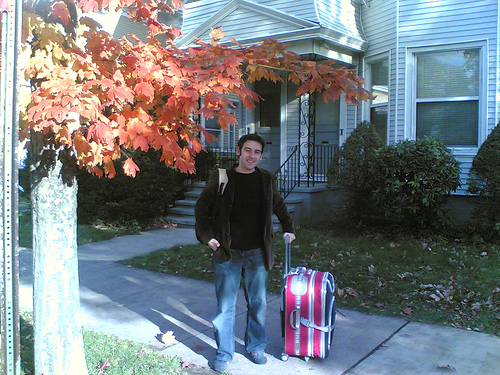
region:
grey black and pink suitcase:
[283, 235, 336, 357]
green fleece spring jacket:
[193, 166, 292, 269]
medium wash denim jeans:
[211, 250, 268, 357]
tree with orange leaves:
[23, 0, 373, 372]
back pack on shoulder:
[213, 167, 229, 211]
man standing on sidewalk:
[193, 133, 296, 370]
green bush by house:
[364, 139, 459, 232]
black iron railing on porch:
[273, 140, 341, 199]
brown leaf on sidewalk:
[160, 326, 175, 348]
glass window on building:
[402, 36, 484, 152]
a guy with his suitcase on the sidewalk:
[150, 121, 407, 373]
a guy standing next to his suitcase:
[188, 125, 343, 373]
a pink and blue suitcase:
[280, 235, 340, 365]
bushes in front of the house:
[326, 107, 438, 247]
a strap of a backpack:
[214, 165, 228, 198]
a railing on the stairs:
[274, 144, 302, 200]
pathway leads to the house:
[80, 223, 202, 263]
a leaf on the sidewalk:
[155, 328, 178, 345]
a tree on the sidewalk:
[21, 30, 366, 372]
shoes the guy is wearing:
[210, 346, 271, 373]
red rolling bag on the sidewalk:
[278, 233, 339, 364]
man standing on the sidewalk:
[192, 128, 299, 374]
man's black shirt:
[227, 164, 265, 257]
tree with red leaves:
[18, 0, 380, 372]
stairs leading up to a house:
[165, 164, 312, 249]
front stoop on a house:
[188, 155, 340, 193]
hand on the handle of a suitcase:
[276, 225, 298, 245]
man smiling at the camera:
[191, 130, 301, 374]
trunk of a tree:
[24, 127, 100, 374]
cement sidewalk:
[16, 240, 497, 373]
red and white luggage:
[281, 269, 342, 360]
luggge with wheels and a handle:
[285, 232, 333, 372]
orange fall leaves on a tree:
[91, 58, 173, 135]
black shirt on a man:
[221, 149, 259, 256]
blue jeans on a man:
[221, 249, 269, 373]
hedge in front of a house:
[355, 128, 472, 252]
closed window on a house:
[410, 23, 487, 157]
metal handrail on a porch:
[274, 75, 334, 207]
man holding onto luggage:
[261, 189, 332, 371]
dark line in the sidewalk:
[357, 330, 404, 372]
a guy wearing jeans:
[189, 128, 301, 373]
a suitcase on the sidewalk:
[276, 235, 340, 367]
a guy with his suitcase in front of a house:
[124, 9, 464, 373]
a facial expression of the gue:
[236, 131, 266, 170]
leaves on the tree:
[24, 3, 365, 177]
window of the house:
[402, 35, 489, 159]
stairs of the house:
[172, 179, 198, 226]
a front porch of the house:
[163, 2, 358, 189]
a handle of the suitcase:
[288, 306, 301, 331]